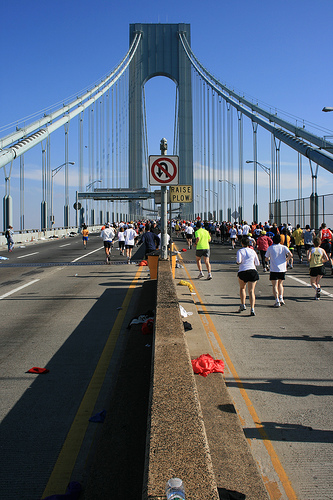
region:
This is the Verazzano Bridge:
[1, 9, 332, 275]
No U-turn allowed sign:
[146, 152, 180, 188]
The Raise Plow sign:
[169, 184, 193, 204]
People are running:
[74, 201, 331, 313]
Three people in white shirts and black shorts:
[102, 221, 138, 264]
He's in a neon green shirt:
[191, 217, 218, 282]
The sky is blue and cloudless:
[2, 1, 332, 168]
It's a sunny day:
[1, 1, 318, 367]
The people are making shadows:
[192, 232, 331, 474]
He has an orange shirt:
[78, 223, 92, 250]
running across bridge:
[4, 22, 318, 491]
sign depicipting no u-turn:
[140, 138, 181, 194]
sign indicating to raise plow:
[168, 180, 201, 213]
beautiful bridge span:
[5, 9, 332, 270]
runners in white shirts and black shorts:
[232, 233, 295, 317]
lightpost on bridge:
[235, 150, 278, 186]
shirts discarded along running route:
[168, 260, 226, 400]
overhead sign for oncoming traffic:
[71, 178, 167, 203]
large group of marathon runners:
[175, 213, 329, 282]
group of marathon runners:
[97, 211, 299, 255]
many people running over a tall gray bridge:
[2, 2, 328, 496]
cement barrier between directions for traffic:
[95, 231, 262, 494]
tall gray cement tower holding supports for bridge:
[119, 18, 197, 219]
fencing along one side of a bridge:
[259, 198, 329, 247]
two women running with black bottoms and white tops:
[231, 233, 293, 312]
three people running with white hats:
[100, 221, 141, 261]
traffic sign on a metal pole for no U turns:
[145, 136, 182, 259]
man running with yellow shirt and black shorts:
[187, 220, 215, 279]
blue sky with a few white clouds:
[0, 4, 322, 223]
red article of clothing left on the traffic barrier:
[191, 351, 227, 383]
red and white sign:
[138, 148, 147, 192]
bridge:
[100, 13, 241, 141]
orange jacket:
[197, 349, 218, 388]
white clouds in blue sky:
[11, 12, 45, 49]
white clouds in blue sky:
[30, 47, 57, 79]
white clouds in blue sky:
[14, 149, 63, 177]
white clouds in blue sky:
[37, 152, 81, 199]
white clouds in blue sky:
[86, 121, 114, 146]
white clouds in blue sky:
[198, 141, 232, 183]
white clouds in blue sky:
[216, 141, 257, 182]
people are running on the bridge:
[64, 199, 331, 320]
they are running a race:
[55, 204, 331, 312]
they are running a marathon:
[56, 209, 331, 314]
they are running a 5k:
[25, 200, 331, 311]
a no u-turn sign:
[146, 152, 181, 186]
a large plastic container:
[145, 247, 180, 280]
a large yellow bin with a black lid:
[147, 247, 176, 282]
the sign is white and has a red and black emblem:
[148, 153, 181, 187]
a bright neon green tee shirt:
[194, 226, 210, 250]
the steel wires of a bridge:
[192, 80, 241, 219]